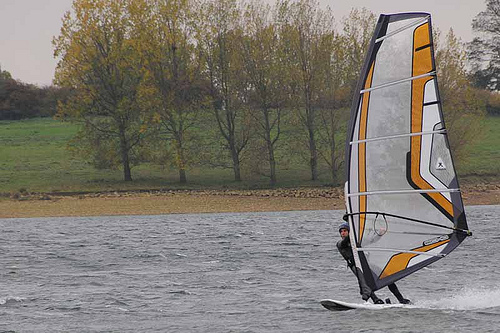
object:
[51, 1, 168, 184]
tree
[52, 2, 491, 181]
woods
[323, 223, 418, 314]
man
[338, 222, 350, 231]
helmet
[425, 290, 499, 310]
splash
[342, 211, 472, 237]
cord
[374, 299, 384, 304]
feet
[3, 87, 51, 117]
tree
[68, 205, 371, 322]
water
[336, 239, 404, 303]
swim suit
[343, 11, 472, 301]
sail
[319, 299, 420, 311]
surfboard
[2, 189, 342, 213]
beach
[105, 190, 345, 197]
rocks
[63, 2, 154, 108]
leaves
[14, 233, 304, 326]
water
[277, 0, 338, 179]
tree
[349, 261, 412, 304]
pants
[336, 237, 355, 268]
jacket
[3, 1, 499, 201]
woods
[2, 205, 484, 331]
water